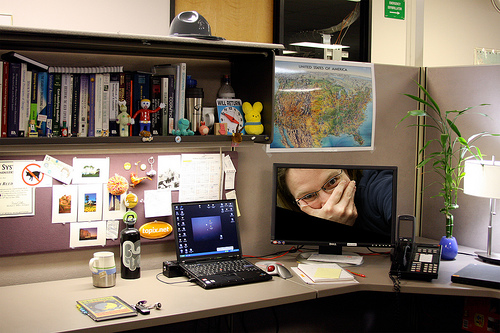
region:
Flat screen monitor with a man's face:
[266, 159, 402, 255]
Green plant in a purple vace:
[394, 73, 499, 264]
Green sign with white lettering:
[383, 0, 408, 22]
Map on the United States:
[265, 53, 377, 153]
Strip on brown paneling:
[170, 1, 276, 47]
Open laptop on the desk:
[168, 194, 276, 294]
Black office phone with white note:
[384, 236, 444, 286]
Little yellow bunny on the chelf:
[238, 97, 266, 137]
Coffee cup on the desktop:
[85, 249, 118, 289]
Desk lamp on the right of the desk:
[460, 154, 499, 269]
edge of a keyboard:
[236, 261, 261, 288]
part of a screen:
[341, 193, 371, 221]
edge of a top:
[316, 270, 338, 300]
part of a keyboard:
[207, 263, 239, 291]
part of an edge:
[278, 236, 288, 251]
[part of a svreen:
[354, 202, 381, 234]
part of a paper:
[313, 266, 337, 296]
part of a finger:
[335, 189, 348, 199]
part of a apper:
[157, 163, 177, 191]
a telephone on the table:
[389, 235, 451, 324]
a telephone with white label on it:
[389, 236, 441, 286]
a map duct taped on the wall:
[267, 60, 419, 163]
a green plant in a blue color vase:
[395, 75, 497, 262]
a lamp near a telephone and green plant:
[391, 88, 497, 285]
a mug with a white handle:
[86, 248, 118, 290]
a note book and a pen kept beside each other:
[74, 293, 137, 320]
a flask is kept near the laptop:
[117, 195, 269, 285]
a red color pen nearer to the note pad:
[291, 261, 369, 282]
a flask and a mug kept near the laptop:
[89, 197, 273, 289]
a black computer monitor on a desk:
[273, 160, 395, 252]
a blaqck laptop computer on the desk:
[164, 195, 272, 286]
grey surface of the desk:
[21, 295, 64, 319]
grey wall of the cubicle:
[448, 76, 475, 94]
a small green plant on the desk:
[415, 98, 472, 252]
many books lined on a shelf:
[16, 68, 169, 117]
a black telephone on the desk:
[393, 233, 447, 285]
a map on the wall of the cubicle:
[277, 61, 379, 158]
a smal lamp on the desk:
[456, 151, 498, 271]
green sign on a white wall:
[381, 0, 408, 25]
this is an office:
[39, 27, 453, 311]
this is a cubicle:
[18, 16, 460, 318]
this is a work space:
[21, 38, 436, 255]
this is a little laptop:
[130, 185, 315, 300]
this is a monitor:
[264, 166, 451, 249]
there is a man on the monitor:
[263, 161, 458, 273]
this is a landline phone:
[373, 213, 471, 285]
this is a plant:
[406, 118, 493, 248]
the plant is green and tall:
[419, 103, 497, 262]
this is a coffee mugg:
[78, 236, 119, 291]